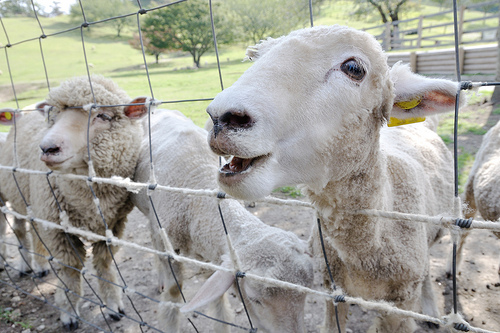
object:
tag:
[383, 94, 424, 128]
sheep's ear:
[389, 64, 467, 122]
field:
[0, 15, 493, 196]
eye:
[341, 57, 371, 83]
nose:
[208, 104, 257, 130]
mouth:
[213, 148, 268, 176]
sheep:
[207, 27, 464, 331]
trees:
[0, 0, 408, 65]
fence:
[356, 1, 496, 81]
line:
[216, 192, 226, 233]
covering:
[246, 271, 326, 299]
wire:
[2, 3, 495, 329]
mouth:
[211, 146, 270, 180]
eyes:
[339, 54, 369, 83]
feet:
[64, 315, 80, 329]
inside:
[387, 90, 456, 110]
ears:
[383, 62, 463, 119]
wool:
[273, 81, 358, 160]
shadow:
[104, 53, 249, 74]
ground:
[2, 14, 497, 328]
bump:
[281, 35, 326, 54]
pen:
[0, 0, 496, 331]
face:
[208, 37, 376, 186]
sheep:
[0, 79, 153, 328]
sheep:
[293, 165, 343, 204]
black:
[314, 100, 377, 133]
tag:
[340, 100, 433, 178]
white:
[298, 133, 334, 153]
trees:
[94, 50, 182, 73]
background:
[18, 102, 364, 150]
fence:
[359, 306, 448, 333]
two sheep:
[34, 50, 344, 220]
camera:
[97, 215, 147, 247]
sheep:
[26, 68, 406, 263]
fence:
[160, 265, 216, 322]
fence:
[142, 248, 183, 294]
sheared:
[152, 119, 364, 333]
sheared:
[2, 127, 143, 333]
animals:
[27, 117, 462, 331]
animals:
[17, 62, 493, 296]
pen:
[162, 99, 209, 114]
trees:
[115, 51, 193, 62]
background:
[29, 128, 494, 293]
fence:
[113, 101, 423, 327]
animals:
[19, 102, 41, 113]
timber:
[462, 99, 494, 108]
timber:
[289, 52, 474, 165]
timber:
[384, 133, 480, 143]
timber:
[426, 51, 444, 66]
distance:
[24, 100, 151, 133]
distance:
[26, 96, 175, 152]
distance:
[117, 116, 203, 244]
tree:
[102, 2, 133, 32]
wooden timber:
[413, 49, 462, 56]